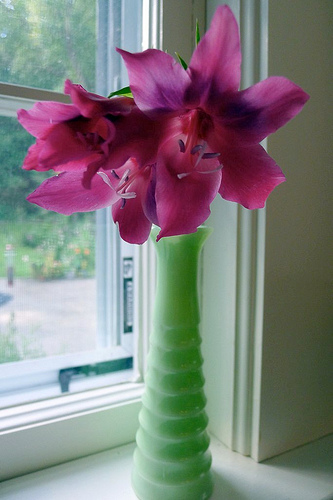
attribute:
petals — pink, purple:
[45, 48, 289, 226]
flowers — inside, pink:
[15, 5, 311, 241]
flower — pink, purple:
[9, 77, 162, 196]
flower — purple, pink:
[14, 16, 311, 245]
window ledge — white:
[2, 421, 330, 499]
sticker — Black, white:
[119, 255, 133, 338]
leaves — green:
[173, 17, 199, 70]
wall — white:
[192, 0, 331, 468]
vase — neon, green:
[124, 225, 252, 490]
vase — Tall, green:
[118, 229, 217, 409]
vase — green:
[151, 254, 197, 493]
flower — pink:
[116, 0, 314, 240]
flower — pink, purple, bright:
[98, 15, 310, 241]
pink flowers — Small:
[18, 2, 310, 243]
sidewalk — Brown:
[0, 275, 106, 356]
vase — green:
[135, 211, 217, 317]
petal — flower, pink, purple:
[200, 77, 309, 146]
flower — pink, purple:
[5, 0, 325, 261]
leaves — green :
[106, 86, 135, 100]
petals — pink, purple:
[110, 41, 188, 115]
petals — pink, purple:
[184, 2, 242, 121]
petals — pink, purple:
[237, 79, 317, 152]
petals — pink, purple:
[211, 133, 286, 214]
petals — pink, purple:
[161, 129, 213, 248]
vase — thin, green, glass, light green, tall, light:
[129, 224, 214, 497]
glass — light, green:
[133, 225, 231, 498]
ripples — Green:
[118, 316, 228, 498]